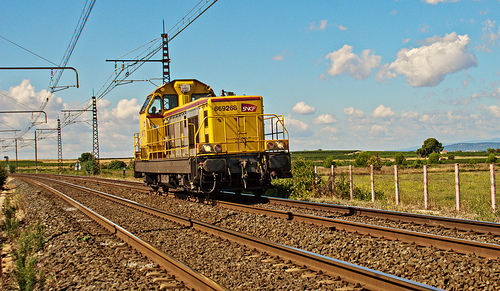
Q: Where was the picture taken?
A: Track.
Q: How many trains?
A: One.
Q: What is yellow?
A: Train.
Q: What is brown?
A: Ground.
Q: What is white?
A: Clouds.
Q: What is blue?
A: Sky.